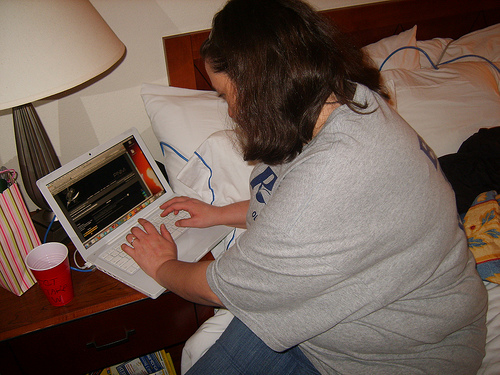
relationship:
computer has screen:
[37, 126, 234, 299] [37, 126, 175, 259]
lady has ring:
[119, 1, 486, 375] [130, 235, 137, 246]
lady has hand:
[119, 1, 486, 375] [121, 217, 220, 307]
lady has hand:
[119, 1, 486, 375] [159, 196, 253, 227]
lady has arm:
[119, 1, 486, 375] [121, 167, 347, 309]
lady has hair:
[119, 1, 486, 375] [194, 1, 391, 167]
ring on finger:
[130, 235, 137, 246] [118, 227, 147, 248]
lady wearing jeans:
[120, 0, 489, 375] [185, 318, 322, 373]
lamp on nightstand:
[1, 3, 126, 230] [2, 202, 220, 373]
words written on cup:
[38, 279, 72, 299] [25, 242, 76, 307]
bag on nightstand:
[1, 168, 44, 296] [7, 199, 234, 366]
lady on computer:
[120, 0, 489, 375] [35, 126, 235, 299]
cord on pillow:
[393, 45, 483, 67] [376, 60, 498, 157]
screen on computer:
[53, 158, 154, 232] [35, 126, 235, 299]